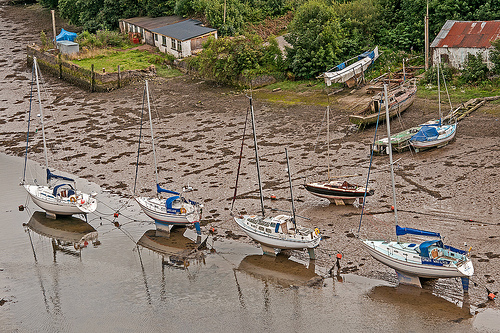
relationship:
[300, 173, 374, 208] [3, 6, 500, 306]
boat in water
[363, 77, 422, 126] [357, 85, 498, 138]
boat on sand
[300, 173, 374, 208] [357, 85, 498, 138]
boat on sand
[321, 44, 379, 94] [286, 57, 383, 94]
boat on grass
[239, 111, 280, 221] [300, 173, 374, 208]
mast on boat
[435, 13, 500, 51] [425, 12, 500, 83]
roof of house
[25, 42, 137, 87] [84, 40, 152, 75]
fence around grass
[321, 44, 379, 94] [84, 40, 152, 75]
boat on grass